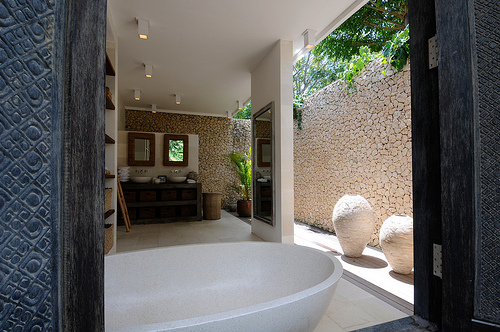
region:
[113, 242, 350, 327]
a large white ceramic bathtub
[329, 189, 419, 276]
two large stone vase statues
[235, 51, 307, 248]
a wall that looks like a pillar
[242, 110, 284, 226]
a large mirror stuck on the wall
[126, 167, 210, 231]
two sinks sitting on a shelf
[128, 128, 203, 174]
two mirrors hanging on the wall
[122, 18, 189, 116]
lights attached to the ceiling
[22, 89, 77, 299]
a blue stone panel with designs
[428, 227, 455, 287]
a white hinge on the wall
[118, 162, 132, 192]
a stack of towels on the counter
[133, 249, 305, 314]
tub on the left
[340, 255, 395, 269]
shadows on the ground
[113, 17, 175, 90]
lights on the wall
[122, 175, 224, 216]
counter in the bathroom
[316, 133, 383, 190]
wall made of cobblestone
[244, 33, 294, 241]
right side of wall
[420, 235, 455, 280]
outlet on the wall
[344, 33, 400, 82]
leaves from the tree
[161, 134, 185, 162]
this is a flower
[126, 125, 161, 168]
this is a flower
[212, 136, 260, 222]
this is a flower pot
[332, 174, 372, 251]
this is a decorative pot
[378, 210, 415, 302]
this is a decorative pot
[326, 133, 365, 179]
the wall is made of small stones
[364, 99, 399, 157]
the wall is made of small stones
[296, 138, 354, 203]
the wall is made of small stones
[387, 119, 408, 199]
the wall is made of small stones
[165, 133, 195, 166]
mirror on the wall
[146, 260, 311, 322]
bathtub in the front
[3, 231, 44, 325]
pattern on the wall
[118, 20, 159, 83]
lights on the wall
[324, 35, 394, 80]
plants over the hedge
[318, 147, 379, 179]
hedge under the tree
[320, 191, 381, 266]
statues on the ground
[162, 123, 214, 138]
pattern on the wall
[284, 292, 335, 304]
rim of the bathtub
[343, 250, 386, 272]
shadow of the statue